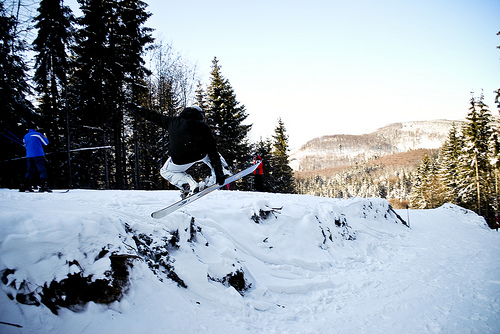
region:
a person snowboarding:
[123, 72, 285, 241]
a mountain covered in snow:
[330, 107, 455, 177]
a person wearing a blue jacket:
[23, 112, 54, 163]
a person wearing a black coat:
[141, 99, 211, 177]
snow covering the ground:
[368, 237, 473, 332]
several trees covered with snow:
[392, 107, 484, 216]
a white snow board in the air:
[150, 172, 243, 224]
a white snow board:
[152, 160, 269, 237]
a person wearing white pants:
[169, 137, 214, 204]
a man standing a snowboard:
[0, 116, 58, 225]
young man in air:
[122, 95, 260, 215]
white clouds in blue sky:
[167, 14, 216, 53]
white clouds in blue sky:
[211, 1, 255, 50]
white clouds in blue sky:
[268, 12, 299, 59]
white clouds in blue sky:
[267, 60, 320, 99]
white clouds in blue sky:
[303, 14, 352, 74]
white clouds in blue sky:
[326, 9, 375, 74]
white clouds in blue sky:
[376, 4, 431, 53]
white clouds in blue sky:
[348, 68, 422, 120]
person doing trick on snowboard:
[137, 84, 265, 206]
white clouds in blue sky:
[178, 6, 219, 44]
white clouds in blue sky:
[238, 32, 287, 82]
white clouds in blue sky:
[278, 5, 333, 58]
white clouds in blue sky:
[300, 63, 338, 104]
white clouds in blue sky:
[316, 78, 365, 116]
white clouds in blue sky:
[337, 16, 371, 47]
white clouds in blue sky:
[362, 20, 428, 58]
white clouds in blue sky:
[373, 46, 433, 109]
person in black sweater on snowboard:
[147, 107, 259, 218]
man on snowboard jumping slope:
[124, 104, 268, 215]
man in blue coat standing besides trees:
[22, 121, 50, 191]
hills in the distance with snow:
[309, 115, 462, 177]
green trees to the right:
[444, 99, 497, 207]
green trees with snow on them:
[469, 98, 493, 209]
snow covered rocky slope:
[349, 196, 391, 232]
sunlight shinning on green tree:
[272, 121, 294, 191]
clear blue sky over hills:
[336, 9, 443, 66]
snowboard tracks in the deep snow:
[200, 214, 323, 281]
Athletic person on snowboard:
[135, 102, 264, 220]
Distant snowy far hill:
[339, 140, 387, 160]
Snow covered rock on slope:
[54, 274, 111, 301]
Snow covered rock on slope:
[136, 223, 168, 262]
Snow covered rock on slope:
[208, 254, 253, 294]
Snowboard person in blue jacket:
[17, 120, 70, 199]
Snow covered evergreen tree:
[438, 116, 482, 209]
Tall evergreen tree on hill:
[273, 120, 298, 192]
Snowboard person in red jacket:
[250, 152, 266, 189]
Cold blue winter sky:
[276, 25, 368, 58]